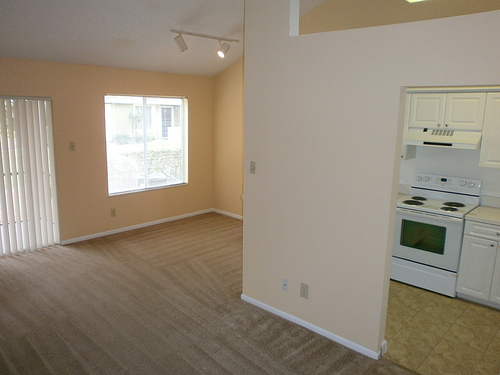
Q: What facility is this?
A: Vacant property.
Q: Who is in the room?
A: No one.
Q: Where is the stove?
A: Kitchen.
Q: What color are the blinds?
A: White.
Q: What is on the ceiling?
A: Lights.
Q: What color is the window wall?
A: Brown.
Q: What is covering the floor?
A: Carpet.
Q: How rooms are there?
A: Three.